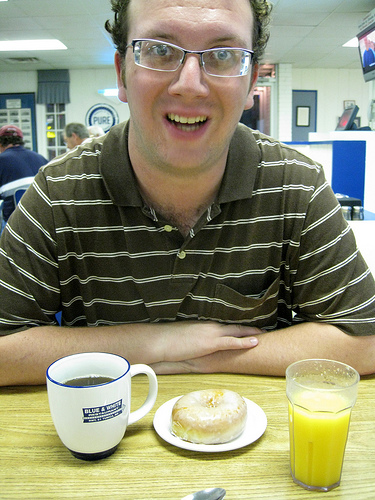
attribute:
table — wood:
[24, 311, 341, 498]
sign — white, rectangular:
[297, 107, 309, 125]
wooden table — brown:
[18, 386, 358, 482]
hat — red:
[1, 123, 22, 136]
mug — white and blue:
[24, 354, 168, 458]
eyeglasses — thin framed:
[141, 37, 255, 86]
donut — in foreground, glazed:
[169, 386, 247, 444]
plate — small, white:
[153, 390, 269, 452]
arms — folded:
[0, 311, 371, 382]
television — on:
[352, 26, 373, 79]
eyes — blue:
[138, 43, 230, 59]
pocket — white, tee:
[217, 274, 282, 324]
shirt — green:
[0, 120, 373, 333]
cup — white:
[40, 345, 160, 467]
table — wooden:
[13, 378, 90, 498]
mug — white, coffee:
[45, 351, 156, 463]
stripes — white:
[48, 186, 114, 262]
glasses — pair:
[126, 36, 254, 77]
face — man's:
[117, 0, 258, 171]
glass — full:
[264, 341, 368, 479]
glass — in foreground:
[282, 356, 359, 495]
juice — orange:
[282, 401, 350, 486]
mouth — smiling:
[132, 100, 225, 154]